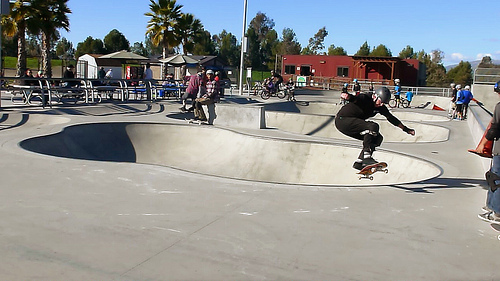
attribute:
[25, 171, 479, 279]
pavement — concrete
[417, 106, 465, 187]
pavement — concrete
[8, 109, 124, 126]
pavement — concrete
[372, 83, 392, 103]
helmet — grey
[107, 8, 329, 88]
trees — tall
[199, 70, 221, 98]
shirt — striped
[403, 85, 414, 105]
boy — little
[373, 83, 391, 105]
head gear — protective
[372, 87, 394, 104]
helmet — gray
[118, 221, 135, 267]
pavement — concrete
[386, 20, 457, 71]
clouds — white, grey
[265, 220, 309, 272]
pavement — concrete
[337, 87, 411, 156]
clothes — black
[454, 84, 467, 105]
top — blue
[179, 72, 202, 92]
shirt — plaid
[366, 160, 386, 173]
bottom — red